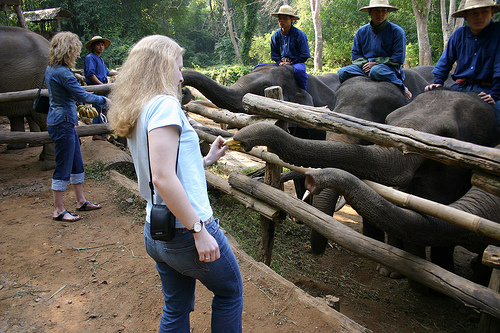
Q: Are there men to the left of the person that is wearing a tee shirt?
A: No, the man is to the right of the lady.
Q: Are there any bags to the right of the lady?
A: No, there is a man to the right of the lady.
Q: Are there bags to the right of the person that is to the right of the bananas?
A: No, there is a man to the right of the lady.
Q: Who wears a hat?
A: The man wears a hat.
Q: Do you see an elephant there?
A: Yes, there is an elephant.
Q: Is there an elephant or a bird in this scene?
A: Yes, there is an elephant.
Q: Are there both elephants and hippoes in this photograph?
A: No, there is an elephant but no hippoes.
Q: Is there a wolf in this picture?
A: No, there are no wolves.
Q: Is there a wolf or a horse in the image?
A: No, there are no wolves or horses.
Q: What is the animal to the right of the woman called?
A: The animal is an elephant.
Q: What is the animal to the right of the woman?
A: The animal is an elephant.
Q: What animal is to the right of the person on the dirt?
A: The animal is an elephant.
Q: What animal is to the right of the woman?
A: The animal is an elephant.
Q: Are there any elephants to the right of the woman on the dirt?
A: Yes, there is an elephant to the right of the woman.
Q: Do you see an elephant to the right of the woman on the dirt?
A: Yes, there is an elephant to the right of the woman.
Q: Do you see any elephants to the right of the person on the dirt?
A: Yes, there is an elephant to the right of the woman.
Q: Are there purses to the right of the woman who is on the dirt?
A: No, there is an elephant to the right of the woman.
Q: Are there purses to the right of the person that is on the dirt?
A: No, there is an elephant to the right of the woman.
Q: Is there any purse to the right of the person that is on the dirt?
A: No, there is an elephant to the right of the woman.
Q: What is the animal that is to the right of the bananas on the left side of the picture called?
A: The animal is an elephant.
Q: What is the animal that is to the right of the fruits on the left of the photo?
A: The animal is an elephant.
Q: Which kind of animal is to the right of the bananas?
A: The animal is an elephant.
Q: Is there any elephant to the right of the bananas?
A: Yes, there is an elephant to the right of the bananas.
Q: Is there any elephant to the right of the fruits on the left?
A: Yes, there is an elephant to the right of the bananas.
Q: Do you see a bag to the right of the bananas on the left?
A: No, there is an elephant to the right of the bananas.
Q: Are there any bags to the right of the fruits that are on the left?
A: No, there is an elephant to the right of the bananas.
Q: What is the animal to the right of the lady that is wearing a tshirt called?
A: The animal is an elephant.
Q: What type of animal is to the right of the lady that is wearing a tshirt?
A: The animal is an elephant.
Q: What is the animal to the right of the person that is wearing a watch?
A: The animal is an elephant.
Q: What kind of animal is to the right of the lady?
A: The animal is an elephant.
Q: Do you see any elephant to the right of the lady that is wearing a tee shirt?
A: Yes, there is an elephant to the right of the lady.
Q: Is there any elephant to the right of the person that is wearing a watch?
A: Yes, there is an elephant to the right of the lady.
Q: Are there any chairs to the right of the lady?
A: No, there is an elephant to the right of the lady.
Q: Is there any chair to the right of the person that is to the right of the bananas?
A: No, there is an elephant to the right of the lady.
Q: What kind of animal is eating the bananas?
A: The animal is an elephant.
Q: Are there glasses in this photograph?
A: No, there are no glasses.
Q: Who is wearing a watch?
A: The lady is wearing a watch.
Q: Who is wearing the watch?
A: The lady is wearing a watch.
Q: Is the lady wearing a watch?
A: Yes, the lady is wearing a watch.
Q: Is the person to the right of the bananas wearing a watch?
A: Yes, the lady is wearing a watch.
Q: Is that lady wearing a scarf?
A: No, the lady is wearing a watch.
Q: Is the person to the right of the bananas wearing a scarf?
A: No, the lady is wearing a watch.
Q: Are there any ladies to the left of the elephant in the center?
A: Yes, there is a lady to the left of the elephant.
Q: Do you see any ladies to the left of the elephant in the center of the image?
A: Yes, there is a lady to the left of the elephant.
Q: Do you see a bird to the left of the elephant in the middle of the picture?
A: No, there is a lady to the left of the elephant.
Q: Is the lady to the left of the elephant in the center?
A: Yes, the lady is to the left of the elephant.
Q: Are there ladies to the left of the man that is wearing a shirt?
A: Yes, there is a lady to the left of the man.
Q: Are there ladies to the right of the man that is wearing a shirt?
A: No, the lady is to the left of the man.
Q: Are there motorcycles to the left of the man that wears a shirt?
A: No, there is a lady to the left of the man.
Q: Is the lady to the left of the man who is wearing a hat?
A: Yes, the lady is to the left of the man.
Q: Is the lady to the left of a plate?
A: No, the lady is to the left of the man.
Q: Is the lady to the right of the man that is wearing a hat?
A: No, the lady is to the left of the man.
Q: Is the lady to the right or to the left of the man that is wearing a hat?
A: The lady is to the left of the man.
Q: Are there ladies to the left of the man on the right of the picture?
A: Yes, there is a lady to the left of the man.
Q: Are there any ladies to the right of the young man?
A: No, the lady is to the left of the man.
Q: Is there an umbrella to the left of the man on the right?
A: No, there is a lady to the left of the man.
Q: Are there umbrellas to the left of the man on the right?
A: No, there is a lady to the left of the man.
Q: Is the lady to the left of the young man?
A: Yes, the lady is to the left of the man.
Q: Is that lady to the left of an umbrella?
A: No, the lady is to the left of the man.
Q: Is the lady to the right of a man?
A: No, the lady is to the left of a man.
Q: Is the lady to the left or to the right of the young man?
A: The lady is to the left of the man.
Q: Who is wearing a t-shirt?
A: The lady is wearing a t-shirt.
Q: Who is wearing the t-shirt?
A: The lady is wearing a t-shirt.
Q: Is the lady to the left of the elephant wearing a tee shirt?
A: Yes, the lady is wearing a tee shirt.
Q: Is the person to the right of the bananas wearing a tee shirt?
A: Yes, the lady is wearing a tee shirt.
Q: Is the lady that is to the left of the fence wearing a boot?
A: No, the lady is wearing a tee shirt.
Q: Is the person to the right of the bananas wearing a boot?
A: No, the lady is wearing a tee shirt.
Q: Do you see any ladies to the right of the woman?
A: Yes, there is a lady to the right of the woman.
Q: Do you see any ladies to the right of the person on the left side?
A: Yes, there is a lady to the right of the woman.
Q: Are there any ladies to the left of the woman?
A: No, the lady is to the right of the woman.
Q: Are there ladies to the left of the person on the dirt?
A: No, the lady is to the right of the woman.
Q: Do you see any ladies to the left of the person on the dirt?
A: No, the lady is to the right of the woman.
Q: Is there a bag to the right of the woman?
A: No, there is a lady to the right of the woman.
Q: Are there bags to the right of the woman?
A: No, there is a lady to the right of the woman.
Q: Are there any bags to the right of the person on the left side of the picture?
A: No, there is a lady to the right of the woman.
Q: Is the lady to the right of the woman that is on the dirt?
A: Yes, the lady is to the right of the woman.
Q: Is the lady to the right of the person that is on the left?
A: Yes, the lady is to the right of the woman.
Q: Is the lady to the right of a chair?
A: No, the lady is to the right of the woman.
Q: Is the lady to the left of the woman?
A: No, the lady is to the right of the woman.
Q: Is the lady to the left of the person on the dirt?
A: No, the lady is to the right of the woman.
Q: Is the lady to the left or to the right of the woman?
A: The lady is to the right of the woman.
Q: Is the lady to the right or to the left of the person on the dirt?
A: The lady is to the right of the woman.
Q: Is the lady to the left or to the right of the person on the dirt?
A: The lady is to the right of the woman.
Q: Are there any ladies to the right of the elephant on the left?
A: Yes, there is a lady to the right of the elephant.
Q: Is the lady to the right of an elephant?
A: Yes, the lady is to the right of an elephant.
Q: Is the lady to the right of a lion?
A: No, the lady is to the right of an elephant.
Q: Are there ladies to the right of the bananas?
A: Yes, there is a lady to the right of the bananas.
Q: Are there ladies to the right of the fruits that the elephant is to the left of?
A: Yes, there is a lady to the right of the bananas.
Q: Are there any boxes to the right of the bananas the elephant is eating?
A: No, there is a lady to the right of the bananas.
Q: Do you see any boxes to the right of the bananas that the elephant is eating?
A: No, there is a lady to the right of the bananas.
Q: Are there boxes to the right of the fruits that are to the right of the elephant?
A: No, there is a lady to the right of the bananas.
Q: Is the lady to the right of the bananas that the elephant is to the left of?
A: Yes, the lady is to the right of the bananas.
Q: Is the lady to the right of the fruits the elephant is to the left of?
A: Yes, the lady is to the right of the bananas.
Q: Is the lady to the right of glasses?
A: No, the lady is to the right of the bananas.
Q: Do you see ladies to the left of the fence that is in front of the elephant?
A: Yes, there is a lady to the left of the fence.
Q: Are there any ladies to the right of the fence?
A: No, the lady is to the left of the fence.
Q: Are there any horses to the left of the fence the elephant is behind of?
A: No, there is a lady to the left of the fence.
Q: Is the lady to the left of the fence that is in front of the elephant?
A: Yes, the lady is to the left of the fence.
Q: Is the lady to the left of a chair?
A: No, the lady is to the left of the fence.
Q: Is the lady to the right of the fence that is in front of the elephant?
A: No, the lady is to the left of the fence.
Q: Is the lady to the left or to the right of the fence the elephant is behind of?
A: The lady is to the left of the fence.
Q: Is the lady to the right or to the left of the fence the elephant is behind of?
A: The lady is to the left of the fence.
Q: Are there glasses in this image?
A: No, there are no glasses.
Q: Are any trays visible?
A: No, there are no trays.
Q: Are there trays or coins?
A: No, there are no trays or coins.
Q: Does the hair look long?
A: Yes, the hair is long.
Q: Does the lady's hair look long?
A: Yes, the hair is long.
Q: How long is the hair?
A: The hair is long.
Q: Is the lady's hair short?
A: No, the hair is long.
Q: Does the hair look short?
A: No, the hair is long.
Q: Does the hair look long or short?
A: The hair is long.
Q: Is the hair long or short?
A: The hair is long.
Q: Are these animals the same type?
A: Yes, all the animals are elephants.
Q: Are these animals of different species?
A: No, all the animals are elephants.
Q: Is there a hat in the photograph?
A: Yes, there is a hat.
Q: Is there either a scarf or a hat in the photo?
A: Yes, there is a hat.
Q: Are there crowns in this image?
A: No, there are no crowns.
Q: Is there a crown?
A: No, there are no crowns.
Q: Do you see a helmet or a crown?
A: No, there are no crowns or helmets.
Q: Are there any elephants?
A: Yes, there is an elephant.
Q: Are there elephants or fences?
A: Yes, there is an elephant.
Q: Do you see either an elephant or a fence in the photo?
A: Yes, there is an elephant.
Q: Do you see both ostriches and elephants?
A: No, there is an elephant but no ostriches.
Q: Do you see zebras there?
A: No, there are no zebras.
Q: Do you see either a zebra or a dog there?
A: No, there are no zebras or dogs.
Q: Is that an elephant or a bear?
A: That is an elephant.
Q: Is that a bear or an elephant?
A: That is an elephant.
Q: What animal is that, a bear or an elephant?
A: That is an elephant.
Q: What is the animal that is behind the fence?
A: The animal is an elephant.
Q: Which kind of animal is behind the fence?
A: The animal is an elephant.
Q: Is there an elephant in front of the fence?
A: No, the elephant is behind the fence.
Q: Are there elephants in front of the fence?
A: No, the elephant is behind the fence.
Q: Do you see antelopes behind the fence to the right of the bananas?
A: No, there is an elephant behind the fence.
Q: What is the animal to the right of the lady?
A: The animal is an elephant.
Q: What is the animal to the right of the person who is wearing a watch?
A: The animal is an elephant.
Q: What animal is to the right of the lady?
A: The animal is an elephant.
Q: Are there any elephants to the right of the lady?
A: Yes, there is an elephant to the right of the lady.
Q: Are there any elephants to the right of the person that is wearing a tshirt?
A: Yes, there is an elephant to the right of the lady.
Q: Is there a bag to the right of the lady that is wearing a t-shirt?
A: No, there is an elephant to the right of the lady.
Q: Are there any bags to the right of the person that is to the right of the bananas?
A: No, there is an elephant to the right of the lady.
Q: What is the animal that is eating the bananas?
A: The animal is an elephant.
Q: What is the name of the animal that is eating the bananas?
A: The animal is an elephant.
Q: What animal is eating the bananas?
A: The animal is an elephant.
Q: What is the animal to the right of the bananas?
A: The animal is an elephant.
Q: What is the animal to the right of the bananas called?
A: The animal is an elephant.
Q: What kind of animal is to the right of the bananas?
A: The animal is an elephant.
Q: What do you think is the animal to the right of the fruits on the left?
A: The animal is an elephant.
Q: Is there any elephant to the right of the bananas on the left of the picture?
A: Yes, there is an elephant to the right of the bananas.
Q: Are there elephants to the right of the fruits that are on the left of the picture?
A: Yes, there is an elephant to the right of the bananas.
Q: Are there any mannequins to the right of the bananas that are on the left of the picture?
A: No, there is an elephant to the right of the bananas.